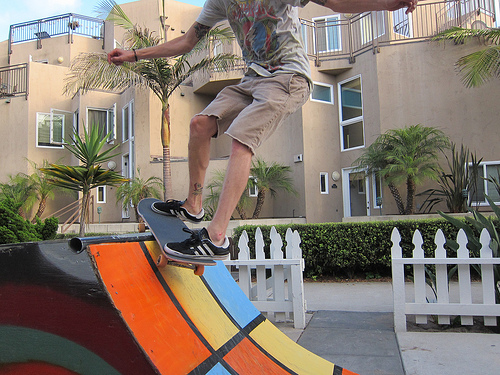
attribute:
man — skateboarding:
[101, 19, 348, 289]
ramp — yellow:
[87, 237, 356, 373]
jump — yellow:
[2, 232, 364, 374]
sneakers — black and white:
[153, 227, 230, 265]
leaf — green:
[387, 128, 408, 149]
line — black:
[189, 312, 266, 373]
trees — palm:
[33, 114, 138, 234]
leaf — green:
[370, 107, 460, 199]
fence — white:
[219, 225, 498, 329]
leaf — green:
[81, 157, 95, 188]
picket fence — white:
[205, 225, 499, 330]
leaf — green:
[7, 220, 12, 224]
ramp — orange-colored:
[47, 222, 237, 334]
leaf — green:
[409, 136, 416, 146]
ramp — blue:
[199, 260, 260, 329]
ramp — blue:
[202, 362, 229, 373]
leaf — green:
[411, 185, 452, 197]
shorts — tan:
[184, 73, 310, 147]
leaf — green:
[98, 138, 127, 161]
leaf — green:
[126, 18, 149, 44]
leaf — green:
[88, 122, 100, 148]